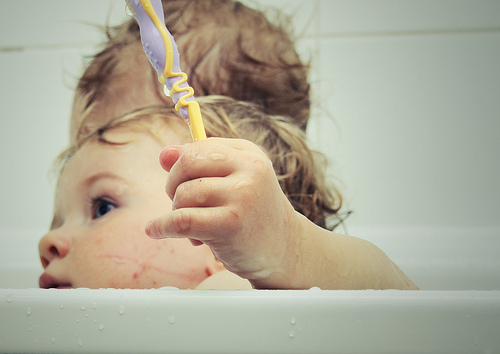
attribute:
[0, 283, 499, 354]
tub — white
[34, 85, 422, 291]
kid — playing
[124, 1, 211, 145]
toothbrush — purple, yellow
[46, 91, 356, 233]
hair — short, blonde, wet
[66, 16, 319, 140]
hair — short, blonde, wet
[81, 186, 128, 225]
eye — blue, dark brown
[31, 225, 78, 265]
nose — small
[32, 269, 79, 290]
mouth — open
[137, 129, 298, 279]
hand — wet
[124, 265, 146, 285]
mark — red